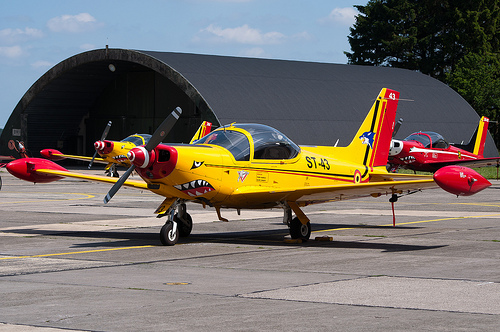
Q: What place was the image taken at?
A: It was taken at the runway.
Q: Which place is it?
A: It is a runway.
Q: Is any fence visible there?
A: No, there are no fences.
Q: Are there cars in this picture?
A: No, there are no cars.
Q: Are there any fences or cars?
A: No, there are no cars or fences.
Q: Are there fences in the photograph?
A: No, there are no fences.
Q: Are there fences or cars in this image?
A: No, there are no fences or cars.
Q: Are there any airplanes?
A: Yes, there is an airplane.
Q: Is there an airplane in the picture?
A: Yes, there is an airplane.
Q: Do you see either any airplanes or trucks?
A: Yes, there is an airplane.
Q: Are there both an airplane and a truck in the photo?
A: No, there is an airplane but no trucks.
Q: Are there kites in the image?
A: No, there are no kites.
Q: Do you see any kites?
A: No, there are no kites.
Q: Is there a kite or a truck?
A: No, there are no kites or trucks.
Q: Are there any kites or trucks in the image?
A: No, there are no kites or trucks.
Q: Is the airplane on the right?
A: Yes, the airplane is on the right of the image.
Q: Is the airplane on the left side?
A: No, the airplane is on the right of the image.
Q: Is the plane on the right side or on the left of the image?
A: The plane is on the right of the image.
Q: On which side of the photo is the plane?
A: The plane is on the right of the image.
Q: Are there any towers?
A: No, there are no towers.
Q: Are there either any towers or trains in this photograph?
A: No, there are no towers or trains.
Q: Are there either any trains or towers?
A: No, there are no towers or trains.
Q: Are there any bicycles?
A: No, there are no bicycles.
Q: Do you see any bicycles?
A: No, there are no bicycles.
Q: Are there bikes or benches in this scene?
A: No, there are no bikes or benches.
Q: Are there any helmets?
A: No, there are no helmets.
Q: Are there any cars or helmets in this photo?
A: No, there are no helmets or cars.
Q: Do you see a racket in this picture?
A: No, there are no rackets.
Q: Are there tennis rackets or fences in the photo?
A: No, there are no tennis rackets or fences.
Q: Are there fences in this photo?
A: No, there are no fences.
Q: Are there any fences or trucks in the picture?
A: No, there are no fences or trucks.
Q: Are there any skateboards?
A: No, there are no skateboards.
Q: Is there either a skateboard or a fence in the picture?
A: No, there are no skateboards or fences.